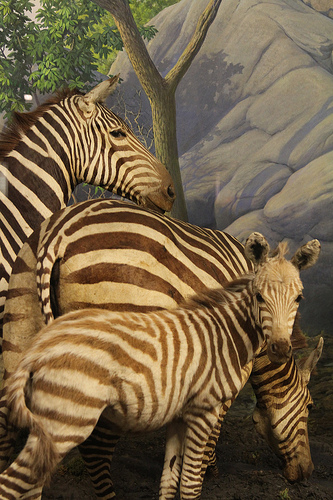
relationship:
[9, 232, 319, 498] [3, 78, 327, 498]
zebra in group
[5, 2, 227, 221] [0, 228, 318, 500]
tree next to zebra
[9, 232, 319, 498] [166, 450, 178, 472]
zebra has spot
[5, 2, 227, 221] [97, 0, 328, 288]
tree next to mountain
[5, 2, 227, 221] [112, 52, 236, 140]
tree has shadow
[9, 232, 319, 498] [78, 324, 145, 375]
zebra has pattern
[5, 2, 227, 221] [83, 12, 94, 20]
tree has leaf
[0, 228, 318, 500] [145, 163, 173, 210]
zebra has nose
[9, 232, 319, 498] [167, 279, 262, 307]
zebra has mane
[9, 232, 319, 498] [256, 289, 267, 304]
zebra has eye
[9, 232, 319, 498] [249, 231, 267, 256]
zebra has ear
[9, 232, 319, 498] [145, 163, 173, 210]
zebra has nose